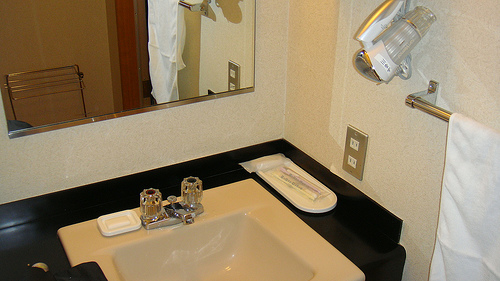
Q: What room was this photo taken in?
A: The bathroom.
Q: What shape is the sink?
A: Square.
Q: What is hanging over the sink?
A: A mirror.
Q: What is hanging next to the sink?
A: A towel.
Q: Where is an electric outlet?
A: On the wall.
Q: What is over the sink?
A: Faucet.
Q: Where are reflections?
A: In the mirror.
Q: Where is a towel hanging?
A: On towel rack.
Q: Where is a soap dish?
A: On the sink.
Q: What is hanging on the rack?
A: White towel.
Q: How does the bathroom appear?
A: Neat and tidy.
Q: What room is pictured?
A: Bathroom.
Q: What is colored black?
A: The countertop.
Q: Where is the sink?
A: In the bathroom.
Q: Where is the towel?
A: On the rack.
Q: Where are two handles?
A: On side the faucet?.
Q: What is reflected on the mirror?
A: A towel.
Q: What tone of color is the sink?
A: White.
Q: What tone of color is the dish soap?
A: White.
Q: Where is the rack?
A: On the wall.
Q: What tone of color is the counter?
A: Black.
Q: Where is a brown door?
A: In the bathroom.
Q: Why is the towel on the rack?
A: To dry hands.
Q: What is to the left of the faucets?
A: Soap.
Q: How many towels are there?
A: One.